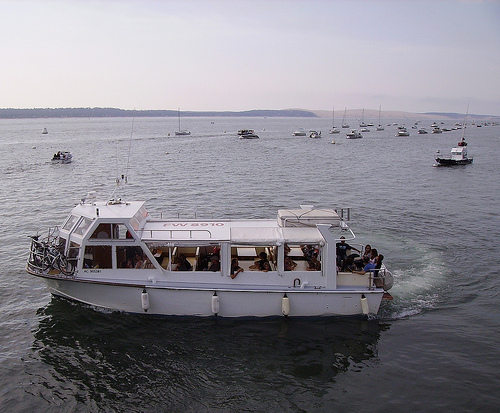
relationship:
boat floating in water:
[432, 142, 477, 166] [0, 117, 493, 405]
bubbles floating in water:
[385, 252, 441, 298] [138, 140, 498, 232]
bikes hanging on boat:
[23, 218, 82, 277] [24, 197, 396, 320]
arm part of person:
[229, 265, 246, 279] [230, 254, 244, 279]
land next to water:
[2, 108, 329, 120] [5, 119, 500, 190]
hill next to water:
[314, 110, 418, 122] [0, 117, 493, 405]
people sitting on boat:
[335, 235, 359, 271] [20, 146, 439, 362]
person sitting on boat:
[354, 243, 373, 272] [20, 146, 439, 362]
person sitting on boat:
[358, 249, 378, 276] [20, 146, 439, 362]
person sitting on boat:
[362, 253, 383, 270] [20, 146, 439, 362]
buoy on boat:
[278, 295, 290, 316] [24, 197, 396, 320]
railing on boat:
[148, 219, 236, 250] [24, 197, 396, 320]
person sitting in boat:
[230, 254, 244, 279] [24, 197, 396, 320]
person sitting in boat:
[254, 250, 272, 270] [24, 197, 396, 320]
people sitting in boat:
[335, 235, 359, 271] [24, 197, 396, 320]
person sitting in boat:
[354, 257, 374, 274] [24, 197, 396, 320]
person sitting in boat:
[130, 252, 145, 267] [24, 197, 396, 320]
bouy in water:
[51, 132, 104, 172] [37, 120, 481, 394]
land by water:
[2, 108, 329, 120] [142, 135, 392, 207]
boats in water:
[265, 112, 485, 167] [154, 150, 402, 205]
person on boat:
[359, 255, 385, 280] [25, 105, 395, 318]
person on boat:
[358, 249, 378, 276] [25, 105, 395, 318]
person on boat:
[354, 243, 373, 272] [25, 105, 395, 318]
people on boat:
[335, 235, 359, 271] [25, 105, 395, 318]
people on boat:
[335, 232, 386, 279] [23, 188, 398, 327]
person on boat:
[354, 243, 373, 272] [24, 197, 396, 320]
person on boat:
[362, 243, 372, 263] [24, 197, 396, 320]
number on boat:
[160, 219, 223, 228] [435, 132, 473, 190]